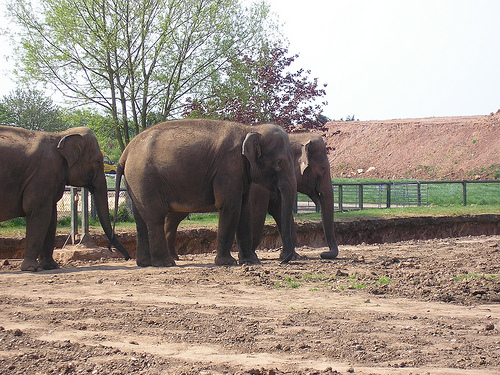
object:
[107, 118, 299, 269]
elephant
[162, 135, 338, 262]
elephant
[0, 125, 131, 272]
elephant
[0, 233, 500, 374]
dirt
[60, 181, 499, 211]
fence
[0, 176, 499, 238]
grass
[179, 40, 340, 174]
tree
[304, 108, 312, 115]
leaves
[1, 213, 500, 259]
ditch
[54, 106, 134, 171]
tree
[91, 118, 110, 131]
leaves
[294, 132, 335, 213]
head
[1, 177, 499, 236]
pasture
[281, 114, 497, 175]
dirt hill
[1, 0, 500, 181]
background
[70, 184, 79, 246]
posts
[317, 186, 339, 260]
trunk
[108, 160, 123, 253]
tail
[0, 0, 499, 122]
sky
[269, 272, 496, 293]
grass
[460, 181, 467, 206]
poles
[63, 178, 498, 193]
rail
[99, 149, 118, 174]
vehicle